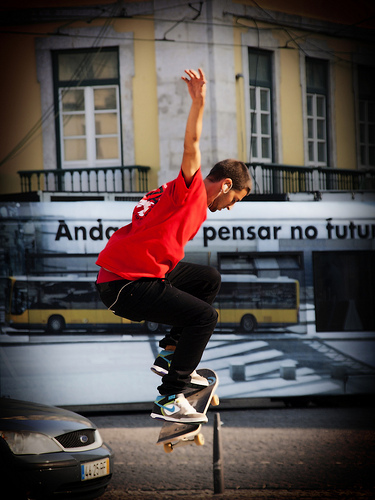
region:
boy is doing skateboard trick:
[107, 66, 242, 469]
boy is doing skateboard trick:
[103, 76, 244, 443]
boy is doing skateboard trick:
[105, 95, 262, 441]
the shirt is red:
[90, 137, 211, 287]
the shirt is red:
[99, 150, 216, 294]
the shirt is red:
[98, 160, 252, 337]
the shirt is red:
[105, 165, 245, 342]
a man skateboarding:
[95, 73, 261, 448]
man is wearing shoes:
[155, 397, 205, 427]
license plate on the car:
[83, 458, 111, 476]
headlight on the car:
[12, 432, 52, 454]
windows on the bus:
[230, 286, 280, 306]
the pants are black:
[178, 302, 208, 328]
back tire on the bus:
[239, 313, 257, 334]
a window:
[252, 121, 272, 159]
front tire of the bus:
[47, 314, 70, 333]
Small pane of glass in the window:
[58, 86, 88, 114]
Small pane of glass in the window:
[89, 84, 116, 114]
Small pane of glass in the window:
[59, 112, 88, 138]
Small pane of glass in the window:
[92, 115, 119, 136]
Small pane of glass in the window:
[60, 138, 85, 158]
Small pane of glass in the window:
[90, 135, 120, 159]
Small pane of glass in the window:
[248, 87, 256, 113]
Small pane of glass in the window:
[258, 85, 269, 112]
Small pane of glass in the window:
[258, 110, 272, 135]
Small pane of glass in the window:
[257, 134, 275, 159]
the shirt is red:
[94, 165, 207, 281]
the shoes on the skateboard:
[150, 348, 208, 422]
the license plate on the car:
[78, 455, 109, 480]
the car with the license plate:
[1, 394, 114, 498]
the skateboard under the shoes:
[157, 367, 219, 454]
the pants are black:
[94, 260, 220, 395]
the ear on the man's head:
[219, 176, 232, 192]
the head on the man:
[205, 159, 251, 212]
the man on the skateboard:
[95, 67, 251, 423]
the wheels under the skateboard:
[163, 393, 219, 452]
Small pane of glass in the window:
[88, 87, 124, 114]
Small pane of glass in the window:
[315, 97, 325, 114]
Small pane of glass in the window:
[314, 117, 327, 141]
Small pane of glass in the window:
[316, 141, 332, 161]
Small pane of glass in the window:
[303, 117, 311, 144]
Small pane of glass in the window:
[306, 93, 311, 116]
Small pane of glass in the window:
[259, 113, 279, 138]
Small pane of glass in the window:
[259, 135, 272, 150]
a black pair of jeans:
[93, 263, 221, 393]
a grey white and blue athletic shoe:
[151, 392, 208, 425]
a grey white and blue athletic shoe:
[152, 347, 208, 387]